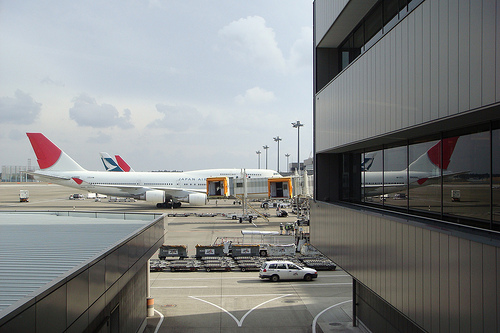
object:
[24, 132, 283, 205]
plane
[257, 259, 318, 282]
car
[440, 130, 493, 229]
window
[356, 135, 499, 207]
reflection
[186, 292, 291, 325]
triangle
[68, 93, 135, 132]
cloud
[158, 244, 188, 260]
carts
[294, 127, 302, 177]
poles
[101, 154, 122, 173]
tail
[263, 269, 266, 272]
tail light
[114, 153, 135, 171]
tail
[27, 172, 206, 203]
wing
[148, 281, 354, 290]
lines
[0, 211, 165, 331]
building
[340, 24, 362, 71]
windows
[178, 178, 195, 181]
japan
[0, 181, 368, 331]
ground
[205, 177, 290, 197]
ramp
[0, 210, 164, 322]
roof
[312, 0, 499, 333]
building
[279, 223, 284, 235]
workers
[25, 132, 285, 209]
airplanes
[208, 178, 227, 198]
opening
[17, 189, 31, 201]
equipment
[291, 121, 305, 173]
light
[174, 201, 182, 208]
wheels